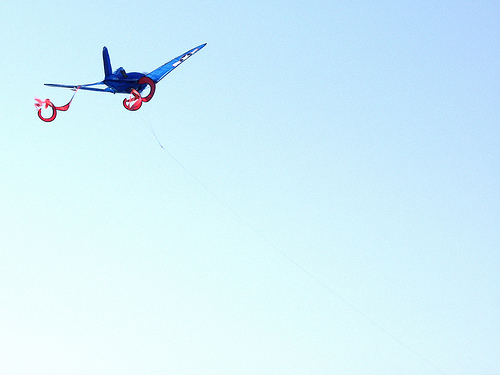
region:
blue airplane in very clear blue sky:
[40, 30, 208, 106]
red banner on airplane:
[37, 90, 87, 126]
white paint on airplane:
[168, 58, 208, 63]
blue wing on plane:
[150, 55, 210, 82]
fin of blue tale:
[95, 50, 115, 70]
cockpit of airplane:
[111, 70, 132, 77]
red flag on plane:
[120, 80, 161, 113]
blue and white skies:
[133, 136, 373, 237]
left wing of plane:
[36, 58, 136, 113]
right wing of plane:
[150, 47, 275, 127]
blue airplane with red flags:
[45, 32, 215, 121]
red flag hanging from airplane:
[31, 96, 76, 123]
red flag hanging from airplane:
[128, 86, 160, 118]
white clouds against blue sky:
[11, 10, 216, 40]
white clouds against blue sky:
[221, 15, 462, 97]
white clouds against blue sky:
[21, 140, 253, 244]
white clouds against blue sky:
[221, 124, 461, 254]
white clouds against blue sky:
[226, 252, 478, 354]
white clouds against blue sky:
[14, 217, 253, 356]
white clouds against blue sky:
[116, 151, 376, 273]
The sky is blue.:
[5, 5, 492, 370]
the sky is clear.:
[5, 5, 494, 370]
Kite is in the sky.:
[30, 33, 207, 128]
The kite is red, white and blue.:
[30, 35, 203, 127]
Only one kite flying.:
[33, 32, 211, 123]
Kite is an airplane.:
[34, 27, 206, 127]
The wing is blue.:
[138, 42, 207, 79]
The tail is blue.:
[92, 38, 115, 82]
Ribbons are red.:
[30, 76, 160, 123]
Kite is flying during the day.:
[5, 6, 492, 367]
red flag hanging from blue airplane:
[31, 93, 78, 129]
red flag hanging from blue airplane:
[126, 77, 155, 110]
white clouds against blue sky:
[19, 133, 181, 358]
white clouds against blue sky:
[157, 122, 341, 353]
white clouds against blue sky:
[306, 121, 480, 333]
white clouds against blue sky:
[218, 18, 335, 212]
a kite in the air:
[32, 10, 339, 207]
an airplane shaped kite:
[9, 21, 334, 180]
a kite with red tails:
[12, 29, 322, 195]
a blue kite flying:
[26, 23, 255, 175]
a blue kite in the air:
[19, 24, 234, 121]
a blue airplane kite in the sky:
[29, 14, 242, 157]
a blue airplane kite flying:
[21, 20, 297, 221]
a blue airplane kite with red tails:
[36, 25, 303, 156]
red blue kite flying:
[9, 10, 286, 147]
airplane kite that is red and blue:
[28, 3, 269, 126]